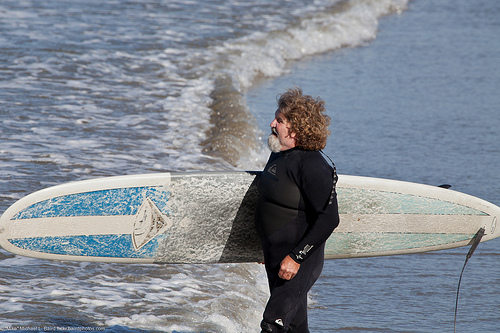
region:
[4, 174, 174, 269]
this end of the surf board is blue and white.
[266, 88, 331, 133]
the man has curly hair.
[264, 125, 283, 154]
the man has a white beard.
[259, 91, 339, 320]
he is wearing a black wetsuit.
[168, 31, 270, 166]
a small brownish wave.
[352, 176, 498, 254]
this end of the surf board is aqua and white.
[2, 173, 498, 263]
the man is carrying a surf board.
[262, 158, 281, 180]
a chevron type of design emblem.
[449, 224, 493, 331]
a tether attached to the surf board.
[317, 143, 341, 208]
a rope/tie hangs from the back of the suit.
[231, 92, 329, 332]
a man walking into the ocean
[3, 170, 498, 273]
the white surfboard the man is holding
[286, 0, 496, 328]
the beach that is next to the ocean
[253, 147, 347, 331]
the wetsuit the man is wearing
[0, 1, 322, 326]
the ocean coming near to the beach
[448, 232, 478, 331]
the cord at the end of the surfboard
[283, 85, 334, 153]
the man's long hair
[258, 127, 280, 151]
the man's white facial hair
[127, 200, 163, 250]
the logo on the surfboard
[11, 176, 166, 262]
the front of the surfboard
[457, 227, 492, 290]
black cord on surf board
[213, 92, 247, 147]
brown section in the sand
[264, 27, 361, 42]
white waves in the sand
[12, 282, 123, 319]
small pebbles in the sand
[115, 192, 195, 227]
small white triangular symbol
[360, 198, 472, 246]
wide white line on skateboard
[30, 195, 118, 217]
bright blue and white section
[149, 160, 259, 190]
silver edge on skate board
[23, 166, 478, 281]
long oblong blue and white skate board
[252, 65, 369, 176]
bushy ginger hair on man's head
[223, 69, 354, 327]
the person is a man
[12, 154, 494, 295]
the board is long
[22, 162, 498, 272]
the board is white and blue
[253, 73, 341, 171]
the hair is brown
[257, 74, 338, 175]
the hair is curly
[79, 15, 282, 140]
the water is rough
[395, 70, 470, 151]
the water is blue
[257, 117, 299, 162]
the beard is white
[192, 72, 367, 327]
the man is white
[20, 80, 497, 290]
the man is holding the board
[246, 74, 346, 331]
A man wearing a black wet suit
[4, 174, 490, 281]
A white and blue surf board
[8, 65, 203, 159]
white foam on the sea water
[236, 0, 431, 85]
a wave rolling into shore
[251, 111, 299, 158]
A man's white goatee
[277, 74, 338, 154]
Longer thick curly hair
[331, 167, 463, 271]
faded turquoise on the board tail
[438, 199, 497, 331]
black strap attached to board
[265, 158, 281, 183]
A Quicksilver wetsuit logo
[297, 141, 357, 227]
a strap runs from the neck to the shoulder of the wetsuit